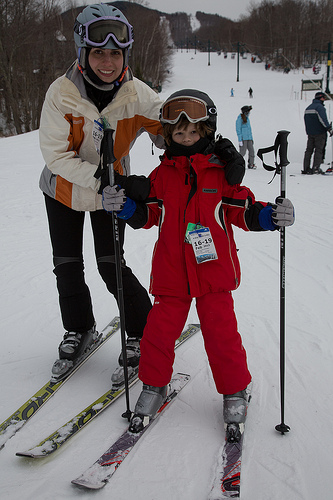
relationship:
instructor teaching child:
[40, 6, 165, 367] [99, 88, 296, 422]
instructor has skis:
[40, 6, 165, 367] [0, 316, 202, 462]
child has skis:
[99, 88, 296, 422] [73, 373, 255, 499]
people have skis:
[39, 4, 294, 424] [0, 317, 249, 499]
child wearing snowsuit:
[99, 88, 296, 422] [133, 153, 254, 394]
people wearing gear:
[39, 4, 294, 424] [74, 3, 217, 144]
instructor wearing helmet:
[40, 6, 165, 367] [75, 3, 133, 93]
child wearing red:
[99, 88, 296, 422] [127, 151, 258, 395]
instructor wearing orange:
[40, 6, 165, 367] [65, 114, 83, 158]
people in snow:
[39, 4, 294, 424] [1, 311, 333, 499]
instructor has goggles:
[40, 6, 165, 367] [83, 18, 135, 48]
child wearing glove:
[99, 88, 296, 422] [272, 197, 295, 229]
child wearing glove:
[99, 88, 296, 422] [102, 186, 127, 213]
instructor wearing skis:
[40, 6, 165, 367] [0, 316, 202, 462]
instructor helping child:
[40, 6, 165, 367] [99, 88, 296, 422]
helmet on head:
[75, 3, 133, 93] [77, 4, 134, 82]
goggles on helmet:
[83, 18, 135, 48] [75, 3, 133, 93]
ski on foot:
[220, 420, 243, 497] [223, 385, 246, 425]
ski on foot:
[74, 371, 193, 492] [134, 386, 170, 418]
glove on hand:
[272, 197, 295, 229] [272, 195, 297, 229]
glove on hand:
[102, 186, 127, 213] [98, 183, 130, 213]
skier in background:
[246, 84, 254, 100] [0, 0, 328, 150]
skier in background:
[228, 87, 235, 99] [0, 0, 328, 150]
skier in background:
[190, 54, 196, 59] [0, 0, 328, 150]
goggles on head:
[159, 95, 212, 124] [161, 87, 215, 153]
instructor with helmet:
[40, 6, 165, 367] [75, 3, 133, 93]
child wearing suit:
[99, 88, 296, 422] [133, 153, 254, 394]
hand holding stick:
[272, 195, 297, 229] [257, 131, 293, 435]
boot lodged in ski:
[223, 390, 247, 425] [220, 420, 243, 497]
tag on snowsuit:
[191, 226, 218, 264] [133, 153, 254, 394]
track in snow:
[242, 437, 332, 499] [1, 311, 333, 499]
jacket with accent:
[39, 74, 167, 212] [57, 175, 74, 209]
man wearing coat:
[302, 91, 331, 177] [304, 99, 332, 137]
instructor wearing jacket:
[40, 6, 165, 367] [39, 74, 167, 212]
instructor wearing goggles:
[40, 6, 165, 367] [83, 18, 135, 48]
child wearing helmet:
[99, 88, 296, 422] [159, 88, 216, 156]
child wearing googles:
[99, 88, 296, 422] [159, 95, 212, 124]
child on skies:
[99, 88, 296, 422] [73, 373, 255, 499]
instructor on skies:
[40, 6, 165, 367] [0, 316, 202, 462]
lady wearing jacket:
[237, 105, 258, 171] [236, 112, 252, 141]